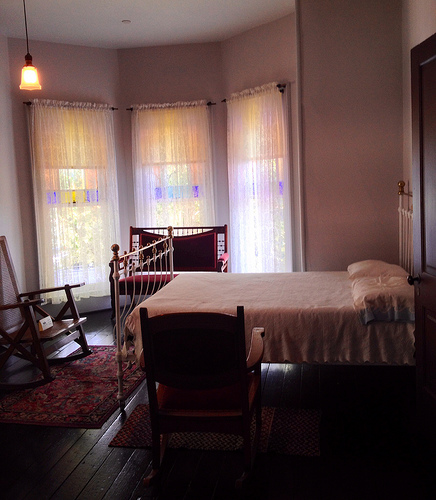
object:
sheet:
[124, 257, 412, 369]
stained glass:
[138, 113, 214, 204]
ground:
[410, 113, 433, 137]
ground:
[366, 153, 401, 185]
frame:
[108, 226, 174, 410]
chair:
[0, 234, 93, 381]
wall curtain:
[227, 83, 341, 270]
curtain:
[128, 95, 217, 237]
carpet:
[108, 397, 333, 452]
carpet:
[0, 342, 148, 430]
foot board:
[110, 226, 174, 411]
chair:
[138, 302, 265, 487]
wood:
[141, 312, 250, 384]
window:
[39, 167, 105, 205]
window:
[140, 162, 206, 199]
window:
[237, 153, 286, 191]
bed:
[108, 225, 416, 414]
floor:
[49, 442, 97, 476]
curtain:
[31, 98, 121, 309]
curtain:
[220, 84, 293, 272]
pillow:
[348, 258, 406, 279]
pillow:
[352, 273, 413, 322]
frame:
[110, 178, 412, 412]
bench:
[109, 223, 229, 327]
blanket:
[123, 271, 414, 365]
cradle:
[66, 223, 245, 290]